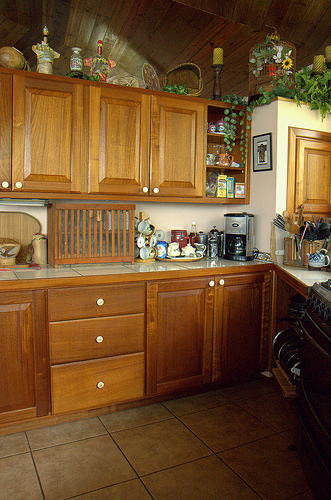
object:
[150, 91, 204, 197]
cabinets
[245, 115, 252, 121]
leaves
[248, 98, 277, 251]
wall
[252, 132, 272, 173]
decoration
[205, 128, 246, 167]
shelves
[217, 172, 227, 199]
food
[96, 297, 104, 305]
knob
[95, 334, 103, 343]
knob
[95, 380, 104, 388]
knob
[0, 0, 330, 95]
ceiling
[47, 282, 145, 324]
drawers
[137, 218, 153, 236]
mugs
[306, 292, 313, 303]
knobs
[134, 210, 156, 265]
holder